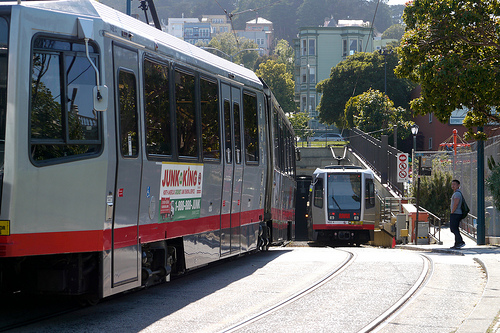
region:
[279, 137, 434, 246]
Train on the tracks.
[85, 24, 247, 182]
Windows on the train.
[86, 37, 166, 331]
Door on the train.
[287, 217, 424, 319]
Track on the road.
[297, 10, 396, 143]
Buildings in the background.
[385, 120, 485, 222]
Signs on the road.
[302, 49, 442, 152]
Trees in the background.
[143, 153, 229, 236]
Logo on the train.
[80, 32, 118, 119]
Mirror on the train.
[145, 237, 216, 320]
Wheel on the bus.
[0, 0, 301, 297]
Silver, white and red train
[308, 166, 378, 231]
Back of red, white and silver train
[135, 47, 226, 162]
Passenger window of train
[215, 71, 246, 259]
Passenger entrance/exit door of train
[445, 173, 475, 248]
Man standing watching train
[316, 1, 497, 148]
tall trees in the distance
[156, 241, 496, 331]
Railroad tracks for trains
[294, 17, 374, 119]
Light yellow building trimed in green in the distance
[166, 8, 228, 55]
White building in the distance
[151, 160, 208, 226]
Advertisement on side of train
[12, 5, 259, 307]
a silver and red train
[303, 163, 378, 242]
a silver and red train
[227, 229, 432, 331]
a set of train tracks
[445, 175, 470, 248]
a pedestrian on sidewalk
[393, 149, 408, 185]
a traffic directional sign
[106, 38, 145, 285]
a train entrance exit door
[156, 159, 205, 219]
a promotional advertisement banner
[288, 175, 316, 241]
a train tunnel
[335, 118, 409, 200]
a black metal fence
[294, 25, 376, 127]
a tall building in distance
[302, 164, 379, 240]
railway car in background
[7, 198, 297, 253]
red stripe on foreground railway car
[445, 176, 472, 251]
man standing on sidewalk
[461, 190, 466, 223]
backpack of man on sidewalk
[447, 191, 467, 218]
gray shirt of man on sidewalk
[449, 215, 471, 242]
black pants of man on sidewalk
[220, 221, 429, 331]
usused railway tracks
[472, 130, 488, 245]
black post beside man on sidewalk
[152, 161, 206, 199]
red and white adversetisement on railway car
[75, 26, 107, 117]
sideview mirror of foreground railway car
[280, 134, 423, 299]
Train riding down the track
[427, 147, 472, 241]
Person standing on side of road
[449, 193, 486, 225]
Person has a backpack on back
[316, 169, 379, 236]
Back of train has a window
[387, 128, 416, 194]
Sign on the side of the road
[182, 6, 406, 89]
buildings in the background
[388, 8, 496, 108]
tall and bushy tree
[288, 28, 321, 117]
Windows on side of building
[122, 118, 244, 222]
Sign on the side of the train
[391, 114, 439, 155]
Street lamp by the road